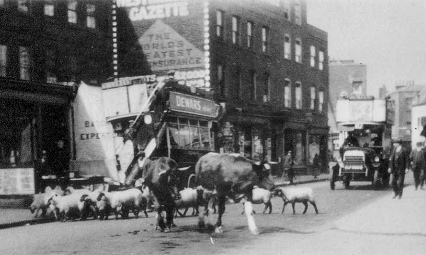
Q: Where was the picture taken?
A: It was taken at the road.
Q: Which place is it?
A: It is a road.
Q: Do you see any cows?
A: Yes, there is a cow.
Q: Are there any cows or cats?
A: Yes, there is a cow.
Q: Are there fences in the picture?
A: No, there are no fences.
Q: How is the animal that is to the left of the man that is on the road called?
A: The animal is a cow.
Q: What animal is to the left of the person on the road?
A: The animal is a cow.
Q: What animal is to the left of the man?
A: The animal is a cow.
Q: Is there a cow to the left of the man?
A: Yes, there is a cow to the left of the man.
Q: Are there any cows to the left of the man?
A: Yes, there is a cow to the left of the man.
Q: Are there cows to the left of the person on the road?
A: Yes, there is a cow to the left of the man.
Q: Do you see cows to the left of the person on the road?
A: Yes, there is a cow to the left of the man.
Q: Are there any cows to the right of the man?
A: No, the cow is to the left of the man.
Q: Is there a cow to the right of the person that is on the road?
A: No, the cow is to the left of the man.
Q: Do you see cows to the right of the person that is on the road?
A: No, the cow is to the left of the man.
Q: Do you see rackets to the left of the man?
A: No, there is a cow to the left of the man.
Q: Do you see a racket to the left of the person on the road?
A: No, there is a cow to the left of the man.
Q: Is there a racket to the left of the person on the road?
A: No, there is a cow to the left of the man.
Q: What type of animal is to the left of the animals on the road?
A: The animal is a cow.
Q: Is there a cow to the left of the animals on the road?
A: Yes, there is a cow to the left of the animals.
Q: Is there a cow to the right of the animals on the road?
A: No, the cow is to the left of the animals.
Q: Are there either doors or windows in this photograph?
A: Yes, there is a window.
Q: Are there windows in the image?
A: Yes, there are windows.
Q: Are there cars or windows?
A: Yes, there are windows.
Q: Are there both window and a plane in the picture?
A: No, there are windows but no airplanes.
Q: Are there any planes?
A: No, there are no planes.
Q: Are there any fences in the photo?
A: No, there are no fences.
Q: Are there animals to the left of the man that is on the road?
A: Yes, there are animals to the left of the man.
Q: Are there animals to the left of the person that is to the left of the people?
A: Yes, there are animals to the left of the man.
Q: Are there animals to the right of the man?
A: No, the animals are to the left of the man.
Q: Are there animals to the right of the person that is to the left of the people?
A: No, the animals are to the left of the man.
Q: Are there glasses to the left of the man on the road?
A: No, there are animals to the left of the man.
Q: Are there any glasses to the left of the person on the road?
A: No, there are animals to the left of the man.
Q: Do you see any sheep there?
A: Yes, there is a sheep.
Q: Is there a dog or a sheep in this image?
A: Yes, there is a sheep.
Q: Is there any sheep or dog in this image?
A: Yes, there is a sheep.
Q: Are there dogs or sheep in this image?
A: Yes, there is a sheep.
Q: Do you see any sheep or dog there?
A: Yes, there is a sheep.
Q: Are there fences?
A: No, there are no fences.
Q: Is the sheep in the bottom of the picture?
A: Yes, the sheep is in the bottom of the image.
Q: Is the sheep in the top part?
A: No, the sheep is in the bottom of the image.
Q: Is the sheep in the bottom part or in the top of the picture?
A: The sheep is in the bottom of the image.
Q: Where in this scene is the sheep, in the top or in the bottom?
A: The sheep is in the bottom of the image.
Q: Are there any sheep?
A: Yes, there is a sheep.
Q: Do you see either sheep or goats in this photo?
A: Yes, there is a sheep.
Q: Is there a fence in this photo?
A: No, there are no fences.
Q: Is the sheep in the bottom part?
A: Yes, the sheep is in the bottom of the image.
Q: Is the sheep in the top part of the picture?
A: No, the sheep is in the bottom of the image.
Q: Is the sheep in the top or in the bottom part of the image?
A: The sheep is in the bottom of the image.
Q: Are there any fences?
A: No, there are no fences.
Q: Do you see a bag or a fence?
A: No, there are no fences or bags.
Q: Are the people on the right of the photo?
A: Yes, the people are on the right of the image.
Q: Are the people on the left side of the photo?
A: No, the people are on the right of the image.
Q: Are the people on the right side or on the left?
A: The people are on the right of the image.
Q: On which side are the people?
A: The people are on the right of the image.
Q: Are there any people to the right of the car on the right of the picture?
A: Yes, there are people to the right of the car.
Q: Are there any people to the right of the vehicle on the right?
A: Yes, there are people to the right of the car.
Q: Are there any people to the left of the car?
A: No, the people are to the right of the car.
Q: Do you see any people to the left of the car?
A: No, the people are to the right of the car.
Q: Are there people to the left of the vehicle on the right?
A: No, the people are to the right of the car.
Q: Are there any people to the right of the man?
A: Yes, there are people to the right of the man.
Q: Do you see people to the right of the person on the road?
A: Yes, there are people to the right of the man.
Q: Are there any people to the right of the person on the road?
A: Yes, there are people to the right of the man.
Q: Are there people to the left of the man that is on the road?
A: No, the people are to the right of the man.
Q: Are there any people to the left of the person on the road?
A: No, the people are to the right of the man.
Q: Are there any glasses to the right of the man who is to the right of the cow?
A: No, there are people to the right of the man.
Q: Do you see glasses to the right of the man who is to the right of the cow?
A: No, there are people to the right of the man.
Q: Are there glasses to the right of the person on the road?
A: No, there are people to the right of the man.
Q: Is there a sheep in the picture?
A: Yes, there is a sheep.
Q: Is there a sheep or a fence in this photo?
A: Yes, there is a sheep.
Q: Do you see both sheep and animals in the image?
A: Yes, there are both a sheep and animals.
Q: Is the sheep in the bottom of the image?
A: Yes, the sheep is in the bottom of the image.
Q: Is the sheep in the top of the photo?
A: No, the sheep is in the bottom of the image.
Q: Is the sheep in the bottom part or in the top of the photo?
A: The sheep is in the bottom of the image.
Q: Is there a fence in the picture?
A: No, there are no fences.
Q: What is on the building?
A: The sign is on the building.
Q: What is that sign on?
A: The sign is on the building.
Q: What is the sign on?
A: The sign is on the building.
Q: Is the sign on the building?
A: Yes, the sign is on the building.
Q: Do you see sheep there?
A: Yes, there is a sheep.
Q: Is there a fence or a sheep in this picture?
A: Yes, there is a sheep.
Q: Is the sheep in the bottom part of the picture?
A: Yes, the sheep is in the bottom of the image.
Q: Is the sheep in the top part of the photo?
A: No, the sheep is in the bottom of the image.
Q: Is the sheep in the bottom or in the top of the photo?
A: The sheep is in the bottom of the image.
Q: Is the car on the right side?
A: Yes, the car is on the right of the image.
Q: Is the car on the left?
A: No, the car is on the right of the image.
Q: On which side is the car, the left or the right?
A: The car is on the right of the image.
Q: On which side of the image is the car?
A: The car is on the right of the image.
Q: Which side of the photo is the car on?
A: The car is on the right of the image.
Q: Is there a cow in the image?
A: Yes, there is a cow.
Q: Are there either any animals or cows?
A: Yes, there is a cow.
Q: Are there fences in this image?
A: No, there are no fences.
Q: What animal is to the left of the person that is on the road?
A: The animal is a cow.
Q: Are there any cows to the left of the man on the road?
A: Yes, there is a cow to the left of the man.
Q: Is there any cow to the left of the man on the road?
A: Yes, there is a cow to the left of the man.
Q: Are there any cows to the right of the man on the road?
A: No, the cow is to the left of the man.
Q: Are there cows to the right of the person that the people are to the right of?
A: No, the cow is to the left of the man.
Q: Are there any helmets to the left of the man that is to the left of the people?
A: No, there is a cow to the left of the man.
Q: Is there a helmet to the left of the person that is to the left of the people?
A: No, there is a cow to the left of the man.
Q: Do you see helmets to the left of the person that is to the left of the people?
A: No, there is a cow to the left of the man.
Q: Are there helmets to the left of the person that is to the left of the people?
A: No, there is a cow to the left of the man.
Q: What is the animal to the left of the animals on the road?
A: The animal is a cow.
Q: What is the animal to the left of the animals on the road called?
A: The animal is a cow.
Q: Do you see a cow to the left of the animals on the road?
A: Yes, there is a cow to the left of the animals.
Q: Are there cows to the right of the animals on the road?
A: No, the cow is to the left of the animals.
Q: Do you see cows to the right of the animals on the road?
A: No, the cow is to the left of the animals.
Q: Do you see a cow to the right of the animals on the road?
A: No, the cow is to the left of the animals.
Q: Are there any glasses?
A: No, there are no glasses.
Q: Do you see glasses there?
A: No, there are no glasses.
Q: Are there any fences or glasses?
A: No, there are no glasses or fences.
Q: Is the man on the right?
A: Yes, the man is on the right of the image.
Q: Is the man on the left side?
A: No, the man is on the right of the image.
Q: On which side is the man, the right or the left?
A: The man is on the right of the image.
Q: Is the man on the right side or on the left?
A: The man is on the right of the image.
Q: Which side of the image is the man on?
A: The man is on the right of the image.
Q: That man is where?
A: The man is on the road.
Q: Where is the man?
A: The man is on the road.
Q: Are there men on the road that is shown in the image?
A: Yes, there is a man on the road.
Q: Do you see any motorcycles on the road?
A: No, there is a man on the road.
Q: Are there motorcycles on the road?
A: No, there is a man on the road.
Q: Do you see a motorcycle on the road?
A: No, there is a man on the road.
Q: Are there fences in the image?
A: No, there are no fences.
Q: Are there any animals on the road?
A: Yes, there are animals on the road.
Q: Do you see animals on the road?
A: Yes, there are animals on the road.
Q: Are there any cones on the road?
A: No, there are animals on the road.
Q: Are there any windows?
A: Yes, there is a window.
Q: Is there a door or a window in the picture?
A: Yes, there is a window.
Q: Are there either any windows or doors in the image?
A: Yes, there is a window.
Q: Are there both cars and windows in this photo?
A: Yes, there are both a window and a car.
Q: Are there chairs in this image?
A: No, there are no chairs.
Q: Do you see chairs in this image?
A: No, there are no chairs.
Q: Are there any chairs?
A: No, there are no chairs.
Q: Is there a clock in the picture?
A: No, there are no clocks.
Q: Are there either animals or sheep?
A: Yes, there is a sheep.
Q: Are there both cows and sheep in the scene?
A: Yes, there are both a sheep and a cow.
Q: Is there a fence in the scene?
A: No, there are no fences.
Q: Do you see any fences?
A: No, there are no fences.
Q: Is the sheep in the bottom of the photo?
A: Yes, the sheep is in the bottom of the image.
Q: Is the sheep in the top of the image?
A: No, the sheep is in the bottom of the image.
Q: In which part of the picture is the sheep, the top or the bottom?
A: The sheep is in the bottom of the image.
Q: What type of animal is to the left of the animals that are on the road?
A: The animal is a sheep.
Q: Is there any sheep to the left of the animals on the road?
A: Yes, there is a sheep to the left of the animals.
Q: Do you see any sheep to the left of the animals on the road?
A: Yes, there is a sheep to the left of the animals.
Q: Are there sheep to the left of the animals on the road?
A: Yes, there is a sheep to the left of the animals.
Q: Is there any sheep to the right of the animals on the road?
A: No, the sheep is to the left of the animals.